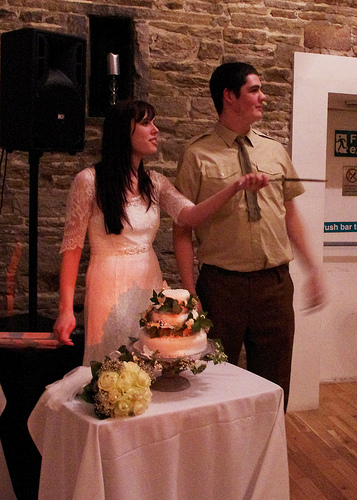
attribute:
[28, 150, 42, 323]
pole — black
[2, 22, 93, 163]
speaker — large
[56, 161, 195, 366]
dress — white, lace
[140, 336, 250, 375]
plate — glass, cake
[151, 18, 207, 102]
wall — brick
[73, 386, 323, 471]
tablecloth — white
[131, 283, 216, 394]
cake — wedding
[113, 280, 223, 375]
cake — decorated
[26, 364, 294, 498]
table cloth — white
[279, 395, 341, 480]
floor — brown, hardwood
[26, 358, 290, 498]
cloth — white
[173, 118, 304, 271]
shirt — tan, brown